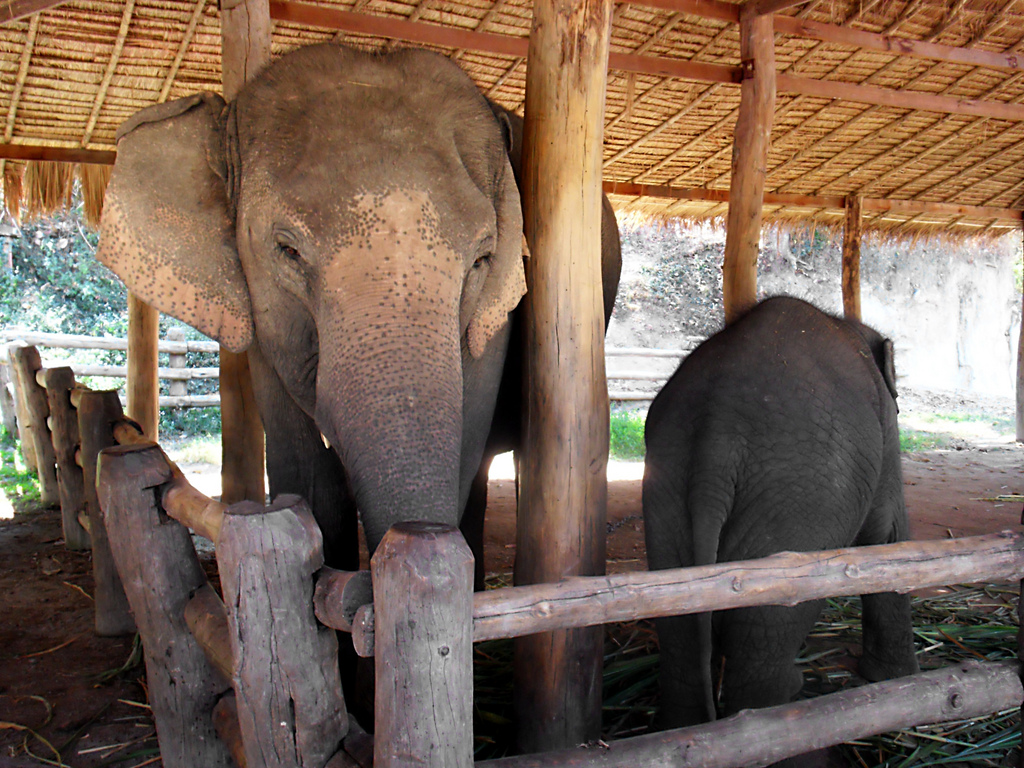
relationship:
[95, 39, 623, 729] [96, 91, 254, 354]
elephant has ear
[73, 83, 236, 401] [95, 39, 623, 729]
ear of elephant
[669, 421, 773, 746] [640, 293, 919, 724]
tail of elephant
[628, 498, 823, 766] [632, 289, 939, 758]
legs of elephant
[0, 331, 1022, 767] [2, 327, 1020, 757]
fence of fence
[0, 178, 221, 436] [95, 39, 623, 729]
vines behind elephant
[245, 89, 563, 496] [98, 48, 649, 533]
face on elephant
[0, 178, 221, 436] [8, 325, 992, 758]
vines on or side of pen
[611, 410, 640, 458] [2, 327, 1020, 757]
grass on other side fence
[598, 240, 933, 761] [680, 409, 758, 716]
elephant has tail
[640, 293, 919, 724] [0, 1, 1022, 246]
elephant under ramada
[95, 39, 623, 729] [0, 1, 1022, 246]
elephant under ramada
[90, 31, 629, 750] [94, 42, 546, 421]
elephant has head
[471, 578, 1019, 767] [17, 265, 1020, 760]
reeds in pen